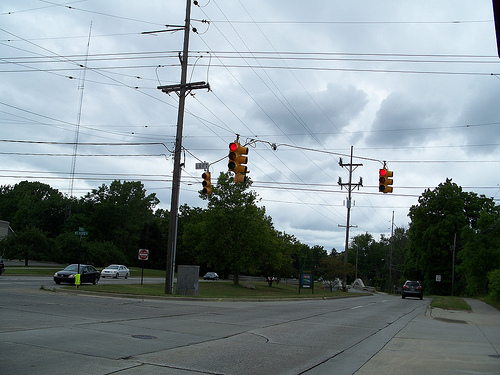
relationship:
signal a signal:
[221, 128, 256, 189] [228, 142, 237, 169]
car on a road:
[53, 264, 100, 285] [0, 271, 498, 375]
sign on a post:
[138, 249, 150, 285] [140, 263, 144, 289]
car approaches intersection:
[101, 265, 131, 279] [12, 280, 499, 375]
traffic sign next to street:
[432, 271, 444, 288] [0, 293, 426, 372]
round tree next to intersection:
[2, 179, 70, 266] [0, 276, 500, 375]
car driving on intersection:
[59, 259, 95, 286] [0, 276, 500, 375]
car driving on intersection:
[99, 257, 134, 282] [0, 276, 500, 375]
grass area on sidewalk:
[427, 292, 472, 313] [388, 291, 499, 373]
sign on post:
[138, 249, 150, 285] [75, 239, 84, 282]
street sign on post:
[68, 222, 94, 237] [75, 239, 84, 282]